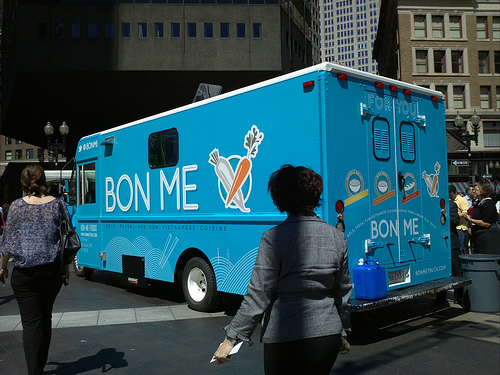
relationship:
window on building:
[189, 23, 197, 39] [1, 5, 323, 84]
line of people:
[451, 245, 499, 246] [449, 174, 499, 272]